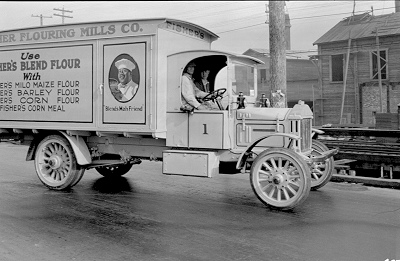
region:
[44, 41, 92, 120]
flour truck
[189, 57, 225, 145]
two people in the truck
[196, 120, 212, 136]
1 on the door of truck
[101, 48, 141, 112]
picture of a baker on the truck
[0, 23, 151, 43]
FISHER FLOURING MILLS CO.is the company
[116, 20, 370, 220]
picture is black and white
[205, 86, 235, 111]
steering wheel is black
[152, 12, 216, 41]
FISHER'S writtin on the front of truck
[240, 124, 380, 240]
front tires are thin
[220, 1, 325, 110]
power line next to the truck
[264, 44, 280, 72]
part of a pole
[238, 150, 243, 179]
edge of a guard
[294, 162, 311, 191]
edge of a wheel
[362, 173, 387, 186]
edge of a road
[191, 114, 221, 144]
Number 1 on the side of truck.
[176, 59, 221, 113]
Driver of the truck.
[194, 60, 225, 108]
Passenger of the truck.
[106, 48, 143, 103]
Painted man with bakers hat.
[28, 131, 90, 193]
Rear driver side tire.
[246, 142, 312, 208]
Front driver side tire.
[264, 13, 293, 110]
Telephone pole near front of truck.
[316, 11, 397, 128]
Building with 2 windows shown.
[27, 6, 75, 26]
Tops of telephone poles.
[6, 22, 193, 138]
Cargo bed of truck.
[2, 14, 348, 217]
vehicle on the road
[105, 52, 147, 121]
picture of a person on the side of the vehicle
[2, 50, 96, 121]
writing on the side of the vehicle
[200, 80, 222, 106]
large black steering whel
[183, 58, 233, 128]
two people in the vehicle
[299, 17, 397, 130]
small wooden building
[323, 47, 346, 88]
window on the side of the building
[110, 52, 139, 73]
large white hat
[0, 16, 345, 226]
old fashioned vehicle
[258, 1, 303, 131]
thick tree trunk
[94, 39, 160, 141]
chef on the side of the car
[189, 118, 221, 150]
the number one on the side of a truck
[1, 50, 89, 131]
writing on the side of a truck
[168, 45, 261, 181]
men driving an old time truck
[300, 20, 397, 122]
old building in the back ground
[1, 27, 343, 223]
old time delivery truck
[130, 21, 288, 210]
old time truck being driven by two guys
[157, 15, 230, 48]
name of the trucks owner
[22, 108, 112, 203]
old style of tires on truck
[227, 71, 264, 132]
lights on the top of a truck